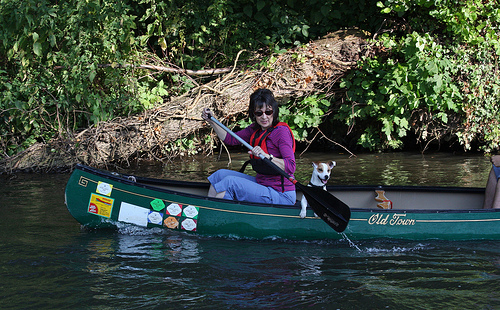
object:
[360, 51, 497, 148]
branch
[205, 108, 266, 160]
handle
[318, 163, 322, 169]
brown patch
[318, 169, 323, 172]
eye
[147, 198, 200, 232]
sticker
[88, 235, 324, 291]
reflection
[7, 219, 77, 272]
water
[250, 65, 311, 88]
bark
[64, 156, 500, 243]
boat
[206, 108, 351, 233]
paddle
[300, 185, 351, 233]
black oar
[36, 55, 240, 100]
branch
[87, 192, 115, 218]
sticker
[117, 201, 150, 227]
stickers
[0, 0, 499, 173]
fallen tree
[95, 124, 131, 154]
bark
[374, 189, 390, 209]
seat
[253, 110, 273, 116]
sunglasses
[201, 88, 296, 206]
person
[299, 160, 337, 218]
animal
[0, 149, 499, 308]
river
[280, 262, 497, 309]
water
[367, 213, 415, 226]
old town